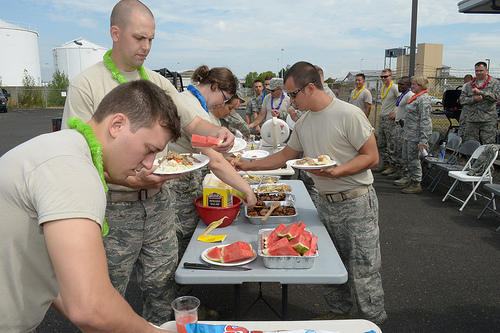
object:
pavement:
[378, 180, 500, 333]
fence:
[0, 81, 68, 114]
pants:
[317, 180, 391, 328]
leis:
[73, 50, 153, 235]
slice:
[190, 134, 223, 150]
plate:
[147, 153, 211, 176]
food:
[200, 154, 336, 270]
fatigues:
[111, 182, 180, 328]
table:
[0, 143, 500, 333]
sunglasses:
[285, 79, 318, 99]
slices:
[260, 221, 318, 259]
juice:
[169, 295, 202, 332]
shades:
[284, 84, 308, 101]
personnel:
[0, 0, 500, 333]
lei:
[469, 74, 491, 88]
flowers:
[63, 117, 111, 238]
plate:
[199, 242, 256, 266]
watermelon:
[261, 221, 319, 259]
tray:
[244, 200, 299, 225]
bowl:
[193, 194, 243, 228]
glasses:
[287, 79, 317, 98]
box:
[202, 185, 233, 208]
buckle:
[326, 192, 346, 203]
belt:
[311, 184, 374, 203]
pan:
[247, 191, 294, 202]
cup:
[170, 295, 200, 332]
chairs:
[441, 144, 500, 212]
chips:
[255, 183, 292, 193]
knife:
[182, 261, 253, 272]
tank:
[52, 39, 112, 80]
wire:
[365, 68, 498, 78]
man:
[229, 60, 388, 327]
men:
[394, 76, 432, 194]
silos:
[0, 22, 43, 91]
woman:
[162, 65, 256, 260]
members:
[0, 0, 500, 333]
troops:
[0, 0, 500, 333]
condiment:
[202, 185, 234, 208]